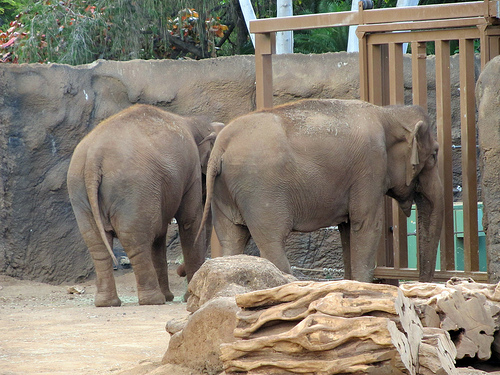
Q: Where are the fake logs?
A: In the elephant cage.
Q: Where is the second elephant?
A: In the cage.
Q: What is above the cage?
A: Grass and weeds.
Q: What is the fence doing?
A: Holding the elephants in.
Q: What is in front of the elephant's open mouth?
A: A trunk.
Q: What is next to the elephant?
A: A gray stone wall.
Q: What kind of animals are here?
A: Elephants.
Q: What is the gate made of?
A: Wood.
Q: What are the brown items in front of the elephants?
A: Logs.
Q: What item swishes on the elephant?
A: Tail.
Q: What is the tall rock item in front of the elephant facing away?
A: A wall.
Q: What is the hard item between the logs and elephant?
A: A boulder.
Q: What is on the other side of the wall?
A: Trees.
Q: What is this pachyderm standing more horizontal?
A: Elephant.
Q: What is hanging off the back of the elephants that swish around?
A: Tails.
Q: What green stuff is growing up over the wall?
A: Grass.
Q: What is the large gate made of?
A: Metal.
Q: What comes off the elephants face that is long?
A: Trunk.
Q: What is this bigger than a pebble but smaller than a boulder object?
A: A Large Rock.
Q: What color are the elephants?
A: Gray.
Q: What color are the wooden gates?
A: Brown.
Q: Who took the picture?
A: A tourist.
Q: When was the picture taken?
A: In the afternoon.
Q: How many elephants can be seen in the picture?
A: Two.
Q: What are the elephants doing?
A: Waiting to be fed.